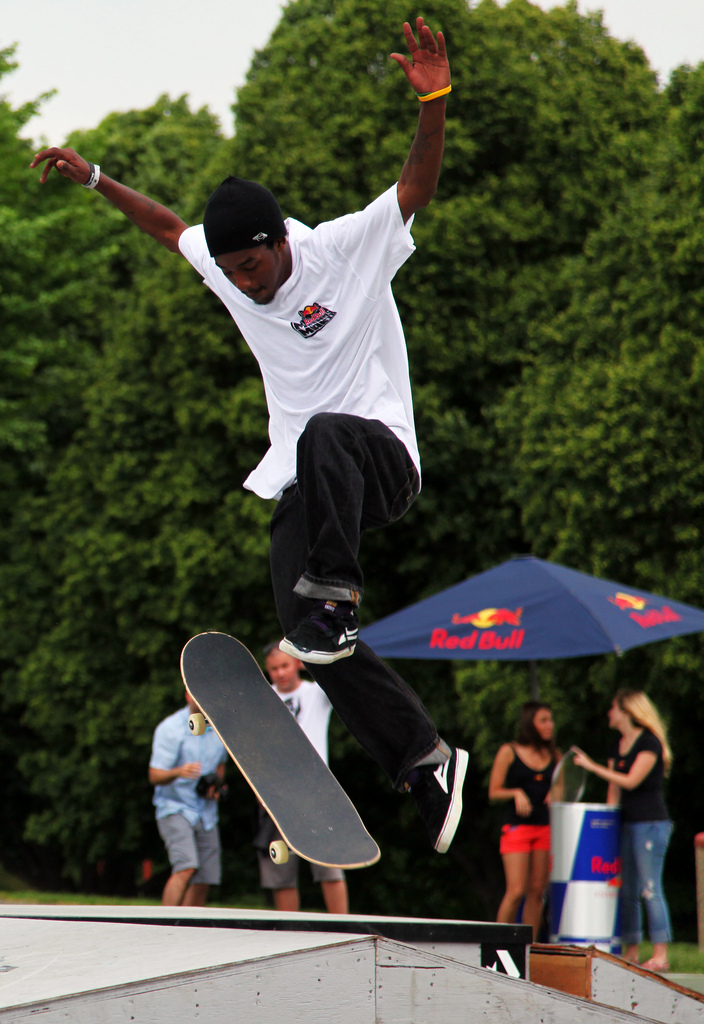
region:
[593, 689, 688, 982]
a person walking on the grass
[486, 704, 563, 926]
a person walking on the grass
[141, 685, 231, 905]
a person walking on the grass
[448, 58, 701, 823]
a tree in a field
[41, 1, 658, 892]
a tree in a field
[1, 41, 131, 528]
a tree in a field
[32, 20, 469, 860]
a person walking on air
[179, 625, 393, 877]
a skateboard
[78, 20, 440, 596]
man up in the air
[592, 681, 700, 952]
woman wearing black shirt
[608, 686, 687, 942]
woman wearing blue jeans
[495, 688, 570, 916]
woman wearing black shirt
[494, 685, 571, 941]
woman wearing red shorts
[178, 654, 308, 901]
skate board in the air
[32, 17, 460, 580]
man wearing white shirt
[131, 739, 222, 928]
man wearing blue shirt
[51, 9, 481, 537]
man wearing black hat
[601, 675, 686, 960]
woman standing near cooler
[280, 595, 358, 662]
black tennis shoes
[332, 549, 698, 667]
Blue sun umbrella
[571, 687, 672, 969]
long blonde haired women standing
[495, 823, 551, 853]
Red short shorts on girl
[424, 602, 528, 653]
Redbull logo on umbrella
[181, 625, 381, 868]
Skateboard in the air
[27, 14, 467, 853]
Skater in middle of a trick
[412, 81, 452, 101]
braclets on the wrist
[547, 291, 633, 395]
green trees with leafs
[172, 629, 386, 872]
the skateboard is black in color.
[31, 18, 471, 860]
the man is wearing black jeans.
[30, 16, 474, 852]
the man is wearing a white shirt.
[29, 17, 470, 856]
the man is wearing black and white shoes.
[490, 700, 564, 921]
the girl is wearing red shorts.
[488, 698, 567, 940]
the girl is wearing a black tank top.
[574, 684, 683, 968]
the girl is wearing blue jeans.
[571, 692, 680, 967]
the girl is wearing a black shirt.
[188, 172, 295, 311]
the man is wearing a black cap.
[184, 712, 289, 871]
the skateboard wheels are whiten in color.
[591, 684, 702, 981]
the woman is blonde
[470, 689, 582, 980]
woman wears black top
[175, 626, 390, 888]
the skateboard is color black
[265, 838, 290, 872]
the wheel is white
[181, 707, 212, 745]
the wheel is white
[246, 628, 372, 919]
man behind a skateboard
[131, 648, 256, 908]
man behind a skateboard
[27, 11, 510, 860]
man in the air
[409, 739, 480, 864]
shoes with white sole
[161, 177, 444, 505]
the shirt is color white